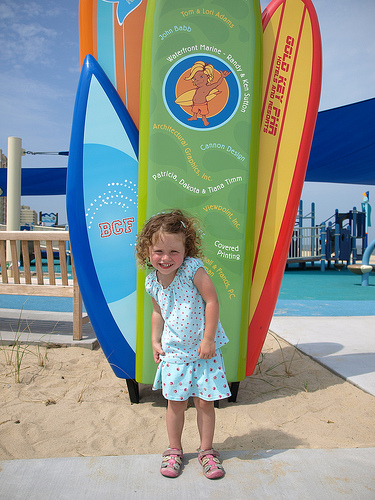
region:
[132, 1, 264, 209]
A green surfboard.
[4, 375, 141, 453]
Sand on the ground.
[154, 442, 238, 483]
Pink shoes.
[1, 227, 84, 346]
A tan bench.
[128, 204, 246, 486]
A little girl standing on a sidewalk.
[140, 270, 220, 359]
A poka dot shirt.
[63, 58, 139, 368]
A blue surfboard.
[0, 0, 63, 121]
Faint clouds in the sky.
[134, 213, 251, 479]
A child that's smiling.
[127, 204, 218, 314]
A little girl with brown hair.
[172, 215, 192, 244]
Clip in girl's hair.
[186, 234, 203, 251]
Girl has brown hair.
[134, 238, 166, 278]
Girl has curly hair.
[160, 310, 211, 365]
Girl wearing blue and pink outfit.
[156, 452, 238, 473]
Person wearing pink and white shoes.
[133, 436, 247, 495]
Girl standing on concrete.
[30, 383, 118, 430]
Sandy area behind girl.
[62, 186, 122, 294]
Blue surfboard behind girl.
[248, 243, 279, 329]
Orange and yellow surfboard behind gird.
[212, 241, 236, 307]
Green surfboard behind girl.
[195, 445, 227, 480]
a girl's pink sandal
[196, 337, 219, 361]
the hand of a girl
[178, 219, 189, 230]
a girl's barrette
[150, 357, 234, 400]
a girls skirt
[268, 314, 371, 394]
part of a sidewalk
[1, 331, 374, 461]
a section of brown sand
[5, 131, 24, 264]
a tall beige pole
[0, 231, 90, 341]
part of a wooden bench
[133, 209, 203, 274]
a girl's brown curly hair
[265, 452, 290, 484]
pieces of dirt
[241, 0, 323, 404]
Red and yellow surfboard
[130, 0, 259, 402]
Green surfboard with picture on it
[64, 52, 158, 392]
Blue surfboard with pointed tip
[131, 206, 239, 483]
Girl in blue dress with red dots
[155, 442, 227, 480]
Pink sandals on young girl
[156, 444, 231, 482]
Pair of pink croc sandals on feet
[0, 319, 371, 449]
Sandy area with some grass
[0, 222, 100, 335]
Wooden bench near pool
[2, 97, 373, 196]
Blue sun cover top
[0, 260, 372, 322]
Clear blue swimmin pool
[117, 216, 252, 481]
a girl standing in front of some surfboards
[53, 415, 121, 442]
tan sand of the beach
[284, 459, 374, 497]
grey concrete of the sidewalk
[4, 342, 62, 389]
several plants growing out of the sand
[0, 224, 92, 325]
a tan wood bench next to the playground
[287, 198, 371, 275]
a blue and grey metal playground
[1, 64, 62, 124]
partly cloudy blue skies over the beach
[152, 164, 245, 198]
white lettering on the green sign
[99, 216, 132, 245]
red lettering on a blue sign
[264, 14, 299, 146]
red lettering on a yellow sign